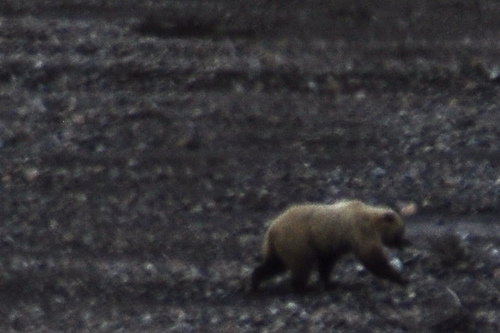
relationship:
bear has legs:
[237, 195, 417, 285] [242, 246, 426, 302]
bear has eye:
[244, 199, 413, 296] [393, 230, 402, 237]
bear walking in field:
[244, 199, 413, 296] [20, 36, 485, 293]